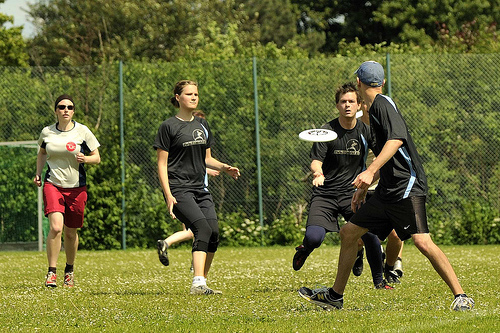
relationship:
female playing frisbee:
[34, 94, 101, 287] [299, 117, 341, 147]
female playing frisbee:
[152, 79, 241, 296] [299, 117, 341, 147]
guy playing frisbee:
[299, 60, 476, 311] [299, 117, 341, 147]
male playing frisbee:
[291, 80, 395, 290] [299, 117, 341, 147]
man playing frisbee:
[366, 103, 368, 113] [299, 117, 341, 147]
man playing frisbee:
[197, 106, 207, 117] [299, 117, 341, 147]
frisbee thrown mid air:
[298, 128, 338, 142] [280, 14, 348, 304]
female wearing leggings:
[152, 79, 241, 296] [168, 186, 229, 253]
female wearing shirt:
[152, 79, 241, 296] [151, 112, 219, 195]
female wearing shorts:
[34, 94, 101, 287] [41, 177, 93, 218]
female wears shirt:
[34, 94, 101, 287] [35, 123, 100, 193]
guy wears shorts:
[299, 60, 476, 311] [373, 203, 433, 235]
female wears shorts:
[34, 94, 101, 287] [37, 184, 87, 218]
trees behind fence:
[1, 1, 488, 59] [1, 61, 499, 248]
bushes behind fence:
[6, 48, 498, 249] [1, 61, 499, 248]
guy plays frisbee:
[299, 60, 476, 311] [290, 123, 346, 150]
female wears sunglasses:
[34, 94, 101, 287] [28, 83, 104, 293]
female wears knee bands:
[152, 79, 241, 296] [182, 199, 220, 240]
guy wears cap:
[293, 52, 478, 315] [350, 54, 390, 94]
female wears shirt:
[152, 79, 241, 296] [152, 112, 215, 184]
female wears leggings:
[152, 79, 241, 296] [168, 186, 229, 253]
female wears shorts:
[34, 94, 101, 287] [41, 177, 93, 218]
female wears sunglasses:
[34, 94, 101, 287] [53, 99, 78, 111]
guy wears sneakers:
[299, 60, 476, 311] [290, 275, 482, 318]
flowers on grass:
[2, 246, 499, 333] [82, 252, 162, 308]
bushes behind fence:
[0, 0, 499, 248] [1, 61, 499, 248]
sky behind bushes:
[6, 4, 44, 34] [32, 4, 99, 62]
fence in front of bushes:
[1, 61, 499, 248] [4, 5, 498, 247]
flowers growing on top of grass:
[2, 254, 498, 324] [4, 249, 494, 332]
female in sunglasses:
[34, 94, 101, 287] [50, 102, 79, 114]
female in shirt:
[152, 79, 241, 296] [157, 120, 218, 185]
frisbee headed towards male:
[297, 129, 338, 149] [291, 80, 395, 290]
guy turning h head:
[299, 60, 476, 311] [352, 62, 388, 98]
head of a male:
[335, 91, 358, 112] [291, 80, 395, 290]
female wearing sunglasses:
[34, 94, 101, 287] [48, 99, 75, 109]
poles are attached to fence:
[113, 57, 284, 239] [12, 65, 484, 232]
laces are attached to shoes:
[296, 275, 482, 318] [298, 280, 481, 316]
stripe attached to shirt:
[388, 137, 415, 171] [365, 95, 421, 193]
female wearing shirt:
[152, 79, 241, 296] [160, 118, 211, 191]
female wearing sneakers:
[34, 94, 101, 287] [35, 259, 83, 286]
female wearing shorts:
[34, 94, 101, 287] [29, 175, 90, 218]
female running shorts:
[34, 94, 101, 287] [40, 183, 88, 221]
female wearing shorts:
[34, 94, 101, 287] [38, 178, 92, 223]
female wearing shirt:
[34, 94, 101, 287] [35, 120, 95, 190]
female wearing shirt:
[34, 94, 101, 287] [42, 126, 97, 196]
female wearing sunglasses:
[34, 94, 101, 287] [54, 92, 66, 114]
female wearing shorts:
[34, 94, 101, 287] [32, 177, 94, 216]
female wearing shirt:
[34, 94, 101, 287] [29, 120, 93, 194]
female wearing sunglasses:
[34, 94, 101, 287] [48, 96, 84, 116]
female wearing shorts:
[152, 79, 241, 296] [166, 171, 220, 206]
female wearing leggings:
[152, 79, 241, 296] [168, 169, 228, 261]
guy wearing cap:
[299, 60, 476, 311] [353, 51, 391, 91]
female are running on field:
[34, 94, 101, 287] [12, 238, 492, 322]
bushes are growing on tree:
[0, 0, 499, 248] [89, 6, 311, 52]